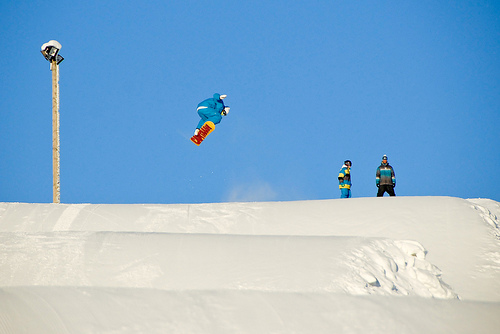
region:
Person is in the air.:
[172, 74, 242, 151]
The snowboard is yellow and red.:
[186, 121, 221, 148]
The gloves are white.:
[211, 85, 235, 112]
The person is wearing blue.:
[170, 75, 232, 140]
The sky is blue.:
[83, 25, 143, 95]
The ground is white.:
[100, 230, 340, 332]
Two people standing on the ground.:
[306, 137, 434, 214]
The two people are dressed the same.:
[323, 143, 415, 199]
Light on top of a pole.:
[21, 28, 87, 89]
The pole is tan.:
[36, 72, 90, 199]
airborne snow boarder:
[180, 75, 242, 148]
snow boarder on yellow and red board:
[191, 114, 219, 151]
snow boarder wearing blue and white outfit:
[190, 74, 235, 126]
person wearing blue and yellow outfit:
[333, 155, 360, 198]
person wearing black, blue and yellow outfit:
[374, 154, 399, 191]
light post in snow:
[26, 24, 84, 197]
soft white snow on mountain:
[23, 208, 250, 318]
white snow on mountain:
[264, 210, 474, 321]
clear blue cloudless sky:
[79, 11, 183, 193]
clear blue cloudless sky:
[246, 14, 482, 150]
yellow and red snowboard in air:
[189, 119, 214, 146]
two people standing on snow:
[339, 154, 397, 199]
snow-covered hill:
[1, 199, 498, 332]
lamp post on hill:
[40, 39, 73, 201]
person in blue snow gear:
[194, 93, 231, 136]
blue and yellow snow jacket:
[337, 163, 353, 187]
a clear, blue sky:
[1, 1, 498, 202]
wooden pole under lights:
[50, 59, 60, 204]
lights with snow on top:
[40, 39, 64, 64]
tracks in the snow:
[50, 201, 267, 229]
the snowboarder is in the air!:
[184, 84, 231, 151]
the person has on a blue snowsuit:
[337, 149, 361, 211]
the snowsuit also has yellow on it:
[336, 143, 359, 223]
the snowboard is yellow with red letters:
[176, 102, 226, 157]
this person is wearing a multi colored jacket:
[376, 143, 397, 202]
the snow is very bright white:
[155, 229, 217, 325]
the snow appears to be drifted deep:
[312, 227, 460, 323]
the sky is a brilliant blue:
[295, 50, 422, 137]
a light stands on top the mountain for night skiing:
[33, 32, 88, 199]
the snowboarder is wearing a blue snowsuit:
[192, 82, 276, 155]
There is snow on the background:
[41, 24, 464, 307]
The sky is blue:
[27, 14, 454, 284]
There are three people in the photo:
[32, 26, 475, 311]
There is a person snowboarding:
[86, 52, 382, 235]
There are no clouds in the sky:
[42, 11, 476, 296]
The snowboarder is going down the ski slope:
[24, 24, 446, 329]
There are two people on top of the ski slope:
[174, 41, 451, 286]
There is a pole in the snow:
[23, 17, 176, 311]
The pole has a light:
[11, 5, 145, 263]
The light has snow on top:
[33, 17, 168, 274]